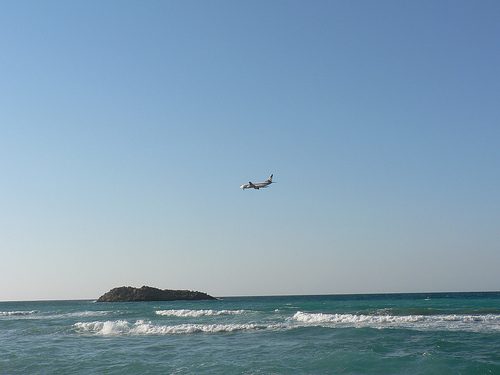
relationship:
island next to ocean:
[95, 285, 221, 300] [0, 291, 500, 374]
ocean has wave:
[0, 291, 500, 374] [71, 309, 500, 338]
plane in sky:
[238, 174, 276, 190] [0, 0, 499, 301]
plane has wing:
[238, 174, 276, 190] [248, 180, 254, 186]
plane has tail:
[238, 174, 276, 190] [267, 173, 274, 183]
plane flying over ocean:
[238, 174, 276, 190] [0, 291, 500, 374]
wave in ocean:
[71, 309, 500, 338] [0, 291, 500, 374]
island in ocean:
[95, 285, 221, 300] [0, 291, 500, 374]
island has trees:
[95, 285, 221, 300] [96, 286, 218, 300]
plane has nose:
[238, 174, 276, 190] [240, 183, 252, 187]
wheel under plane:
[255, 186, 262, 189] [238, 174, 276, 190]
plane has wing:
[238, 174, 276, 190] [265, 178, 276, 183]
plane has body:
[238, 174, 276, 190] [242, 182, 270, 188]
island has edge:
[95, 285, 221, 300] [97, 286, 140, 302]